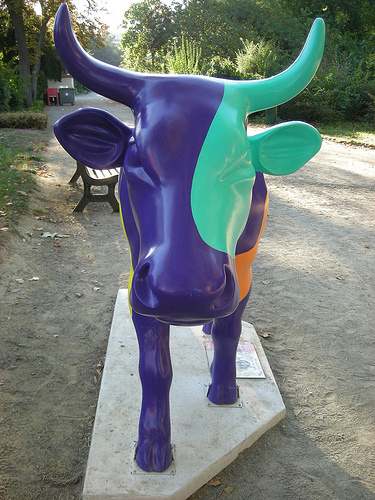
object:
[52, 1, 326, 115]
horns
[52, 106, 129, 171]
ear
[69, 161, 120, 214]
bench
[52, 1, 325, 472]
bull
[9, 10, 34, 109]
trunk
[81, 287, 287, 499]
foundation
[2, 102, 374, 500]
sand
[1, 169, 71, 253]
leaves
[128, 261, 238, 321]
nose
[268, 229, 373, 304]
tracks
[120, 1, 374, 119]
trees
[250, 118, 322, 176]
left ear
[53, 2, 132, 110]
right horn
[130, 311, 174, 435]
leg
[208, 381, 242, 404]
hoof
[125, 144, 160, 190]
eye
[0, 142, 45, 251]
grass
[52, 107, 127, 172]
right ear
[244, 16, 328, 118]
horn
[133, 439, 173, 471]
hoof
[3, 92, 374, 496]
ground